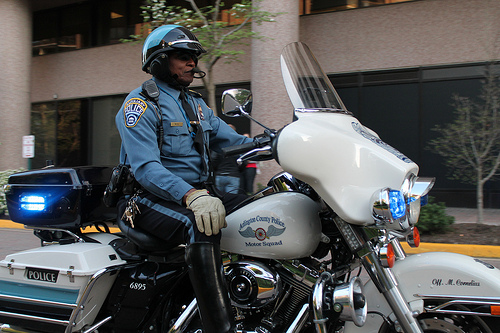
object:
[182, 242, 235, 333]
boot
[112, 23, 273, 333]
cop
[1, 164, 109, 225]
case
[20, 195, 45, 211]
light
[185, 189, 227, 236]
glove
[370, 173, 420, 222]
headlight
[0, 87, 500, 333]
motorcycle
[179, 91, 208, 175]
tie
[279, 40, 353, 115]
wind shield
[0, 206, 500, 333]
ground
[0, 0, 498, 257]
building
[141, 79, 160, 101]
radio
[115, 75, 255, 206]
shirt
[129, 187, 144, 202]
key chain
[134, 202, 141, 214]
key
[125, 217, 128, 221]
key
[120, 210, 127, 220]
key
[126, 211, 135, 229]
key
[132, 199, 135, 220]
key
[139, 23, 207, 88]
helmet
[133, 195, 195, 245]
blue stripe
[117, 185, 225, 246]
pants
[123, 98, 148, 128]
patch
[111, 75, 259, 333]
uniform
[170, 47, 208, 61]
sunglasses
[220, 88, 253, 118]
mirror